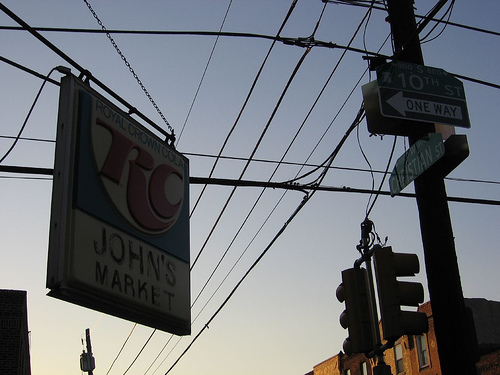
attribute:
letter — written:
[87, 119, 156, 214]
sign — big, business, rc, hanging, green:
[47, 84, 212, 330]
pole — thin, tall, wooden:
[401, 185, 496, 340]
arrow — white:
[386, 86, 458, 121]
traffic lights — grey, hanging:
[326, 229, 423, 368]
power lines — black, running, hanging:
[240, 43, 347, 184]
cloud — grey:
[297, 232, 334, 271]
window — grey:
[407, 334, 440, 371]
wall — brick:
[1, 328, 31, 374]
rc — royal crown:
[75, 97, 189, 237]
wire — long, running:
[234, 175, 283, 199]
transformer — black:
[277, 25, 335, 59]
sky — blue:
[156, 48, 198, 88]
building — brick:
[1, 274, 65, 374]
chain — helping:
[114, 37, 142, 86]